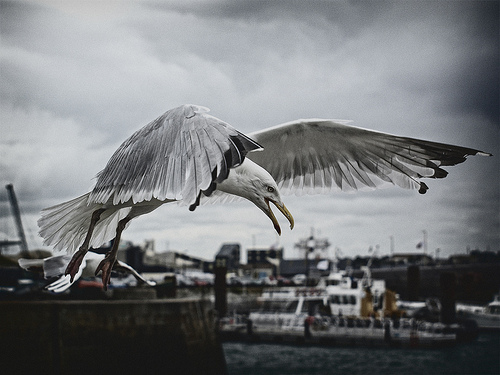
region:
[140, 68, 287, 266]
This is a large white bird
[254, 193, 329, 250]
This is a beak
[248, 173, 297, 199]
This is an eye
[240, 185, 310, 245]
The beak is yellow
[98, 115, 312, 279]
There are two wings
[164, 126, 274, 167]
The wing is grey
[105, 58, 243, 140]
The sky is very cloudy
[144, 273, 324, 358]
This is a harbor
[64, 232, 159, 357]
These are large feet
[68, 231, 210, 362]
The feet are webbed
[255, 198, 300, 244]
The seagull's yellow beak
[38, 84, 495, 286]
White and black seagull in mid flight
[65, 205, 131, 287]
The seagull's legs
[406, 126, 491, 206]
Black feathers on the tip of the left wing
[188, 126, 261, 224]
Black feathers on the tip of the right wing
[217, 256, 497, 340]
Sail boat in the background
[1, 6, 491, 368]
Boat dock in the background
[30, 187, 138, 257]
White seagull tail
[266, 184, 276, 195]
Seagull's eye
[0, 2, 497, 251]
Dark cloudy grey sky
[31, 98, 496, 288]
A bird in the foreground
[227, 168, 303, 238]
A side view of a bird's head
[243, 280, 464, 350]
A boat in the background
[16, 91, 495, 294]
The bird is white and gray in color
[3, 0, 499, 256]
The sky is gray in color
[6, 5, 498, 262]
The sky is cloudy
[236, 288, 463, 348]
The boat is white in color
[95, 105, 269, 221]
Birds wing is gray in color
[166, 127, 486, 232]
The end of the birds wing is black in color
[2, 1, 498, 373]
Photo was taken outdoors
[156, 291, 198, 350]
part of a fence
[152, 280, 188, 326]
edge of a fence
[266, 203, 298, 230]
the front beak of the bird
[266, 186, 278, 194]
it is the eye of the bird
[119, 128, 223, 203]
the birds left side of the wing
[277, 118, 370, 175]
the birds right side of wings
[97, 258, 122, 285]
the birds foot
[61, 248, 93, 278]
it is the other side of the birds foot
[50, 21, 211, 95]
dark clouds in the background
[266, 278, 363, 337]
ships in the background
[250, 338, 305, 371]
water is in the background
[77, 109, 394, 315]
a bird is taking off to fly